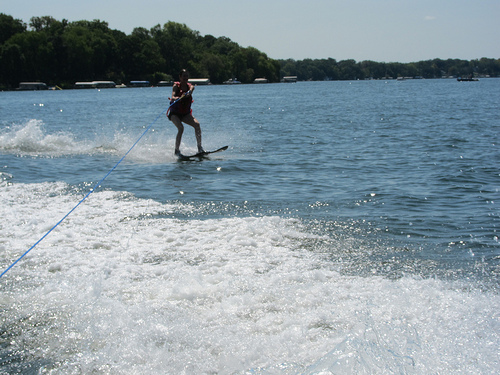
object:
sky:
[0, 1, 499, 71]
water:
[0, 78, 498, 374]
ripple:
[0, 81, 499, 375]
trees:
[1, 11, 285, 88]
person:
[165, 68, 202, 157]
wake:
[0, 180, 500, 374]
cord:
[0, 97, 177, 277]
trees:
[274, 57, 499, 82]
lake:
[0, 78, 499, 375]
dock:
[18, 82, 48, 90]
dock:
[75, 81, 116, 89]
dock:
[129, 80, 149, 86]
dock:
[188, 78, 211, 84]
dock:
[253, 78, 269, 84]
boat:
[457, 75, 479, 82]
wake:
[0, 117, 194, 167]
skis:
[175, 145, 229, 163]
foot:
[198, 147, 205, 154]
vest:
[167, 81, 193, 120]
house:
[473, 72, 491, 78]